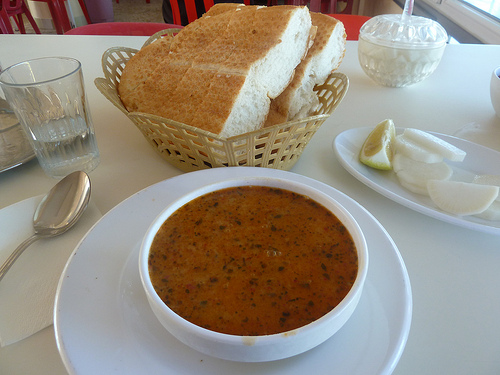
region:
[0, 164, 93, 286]
a metal spoon on the table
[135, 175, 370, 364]
a white porcelain bowl on the table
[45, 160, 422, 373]
a white porcelain plate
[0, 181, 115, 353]
a white napkin on the table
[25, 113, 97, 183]
water in the glass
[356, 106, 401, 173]
a slice of lemon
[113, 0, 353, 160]
bread in the basket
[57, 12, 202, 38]
a red chair at the table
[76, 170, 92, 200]
light reflecting on the spoon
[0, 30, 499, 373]
a white table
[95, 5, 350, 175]
white bread in a basket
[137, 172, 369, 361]
soup in a white bowl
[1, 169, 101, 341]
silver spoon on a white napkin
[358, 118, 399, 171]
slice of lemon on plate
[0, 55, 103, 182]
small amount of water in clear glass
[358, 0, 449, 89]
glass container of sugar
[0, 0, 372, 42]
red chairs at table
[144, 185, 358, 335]
green seasonings in orange soup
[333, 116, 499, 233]
white and yellow slices on plate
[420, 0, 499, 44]
bottom of window trim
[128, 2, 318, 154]
White bread in a basket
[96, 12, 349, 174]
Basket full of bread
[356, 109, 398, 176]
Lemon wedge sitting on a plate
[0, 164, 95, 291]
Spoon sitting on a napkin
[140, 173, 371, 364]
Bowl of soup sitting on a dinner plate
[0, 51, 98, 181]
Drinking glass sitting on the table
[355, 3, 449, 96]
Container to store sugar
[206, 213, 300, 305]
Herbs floating in soup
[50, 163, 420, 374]
Dinner plate sitting on the table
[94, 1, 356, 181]
Breadbasket sitting on the table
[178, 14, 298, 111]
french bread cut into pieces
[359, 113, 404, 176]
lemon wege on plate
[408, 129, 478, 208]
white pieces of fruit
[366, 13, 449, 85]
glass round container on table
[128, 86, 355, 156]
tan colored bread basket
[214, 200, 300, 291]
red colored seasoned soup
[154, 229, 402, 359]
white bowl with soup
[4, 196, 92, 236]
silver spoon on napkin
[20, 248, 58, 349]
white napkin table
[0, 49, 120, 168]
glass cup with water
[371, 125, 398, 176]
The lemon wedge on the white plate.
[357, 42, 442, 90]
The sugar in the glass bowl.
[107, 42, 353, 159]
The basket holding the bread.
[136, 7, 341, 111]
The bread in the basket.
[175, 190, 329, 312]
The soup in the white bowl.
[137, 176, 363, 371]
The white bowl the soup is in.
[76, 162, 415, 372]
The white plate under the bowl of soup.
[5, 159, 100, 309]
The spoon on the left of the soup.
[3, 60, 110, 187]
The glass of water.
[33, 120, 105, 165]
The water in the glass.